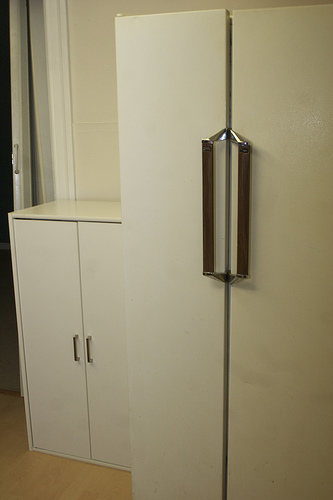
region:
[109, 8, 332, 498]
Side by side refrigerator is white.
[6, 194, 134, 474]
Cabinet beside refrigerator.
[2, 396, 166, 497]
There is wood flooring.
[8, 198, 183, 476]
Cabinet has two doors.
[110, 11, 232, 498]
Freezer door handle has woodgrain.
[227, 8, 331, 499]
Refrigerator handle has woodgrain.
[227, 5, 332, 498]
Refrigerator is on the right.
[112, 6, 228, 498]
Freezer is on the left.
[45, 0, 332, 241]
Wall behind refrigerator is white.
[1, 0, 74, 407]
Door next to cabinet is open.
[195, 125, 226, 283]
a brown refrigerator handle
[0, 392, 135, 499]
a brown wooden floor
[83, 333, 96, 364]
a brown handle on the cabinet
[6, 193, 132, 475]
a cream colored metal cabinet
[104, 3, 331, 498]
a cream colored refridgerator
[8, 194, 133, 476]
the cabinet doors are closed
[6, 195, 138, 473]
the cabinet sits directly on the floor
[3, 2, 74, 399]
an open doorway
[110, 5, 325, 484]
the refrigerator sits next to the cabinet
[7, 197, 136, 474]
the cabinet is shorter than the refrigerator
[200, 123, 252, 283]
Brown and silver fridge handles.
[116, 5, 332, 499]
Tall white fridge with brown handles.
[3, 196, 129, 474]
Small white cupboard on floor.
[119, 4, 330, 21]
Top of white fridge.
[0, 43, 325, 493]
Fridge and cupboard on floor.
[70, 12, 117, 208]
Wall in background of kitchen.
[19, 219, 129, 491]
White cupboard with two doors.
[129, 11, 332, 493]
Tall white fridge with two doors.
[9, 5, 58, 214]
Side door in kitchen.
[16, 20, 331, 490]
Kitchen area with fridge and cupboard.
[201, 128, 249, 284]
Two brown wooden handles fastened by metal.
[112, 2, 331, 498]
A white metal cabinet.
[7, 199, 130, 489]
A smaller white metal cabinet.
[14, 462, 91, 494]
A light colored wooden floor.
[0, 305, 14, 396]
The darkened hallway before the room.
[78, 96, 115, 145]
A white wall in the background.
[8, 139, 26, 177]
An off-white handle on a the slide door.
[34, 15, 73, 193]
The white paneling around the entryway.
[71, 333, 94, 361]
Two brown wooden handles on the smaller cabinet doors.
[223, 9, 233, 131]
A slight opening in the larger cabinet.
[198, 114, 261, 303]
silver and wooded door handles on a white refrigerator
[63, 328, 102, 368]
silver door handles on an adjacent cabinet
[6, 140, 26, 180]
a silver handle on a door in the background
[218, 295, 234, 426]
the seam of the doors of the refrigerator coming together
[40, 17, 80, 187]
the white edging to the door frame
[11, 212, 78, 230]
a gap in the cabinet between the door and the top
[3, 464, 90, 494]
a blond wood laminate floor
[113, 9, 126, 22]
the top edge of the refrigerator door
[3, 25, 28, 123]
a white edge to the door of the room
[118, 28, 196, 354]
a very clean white door of the refrigerator